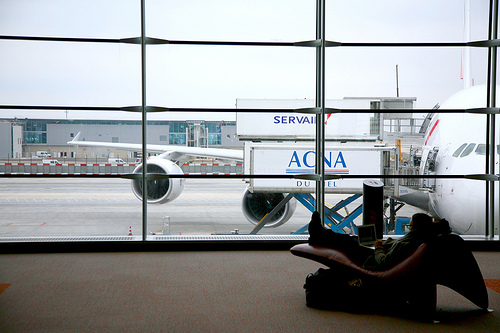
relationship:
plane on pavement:
[65, 5, 498, 243] [3, 178, 424, 245]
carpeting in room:
[7, 252, 498, 323] [0, 7, 499, 327]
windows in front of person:
[6, 4, 493, 239] [311, 205, 454, 275]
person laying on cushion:
[307, 210, 432, 270] [293, 237, 497, 322]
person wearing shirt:
[311, 205, 454, 275] [374, 232, 418, 268]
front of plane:
[433, 136, 499, 238] [58, 5, 498, 243]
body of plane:
[422, 81, 497, 237] [58, 5, 498, 243]